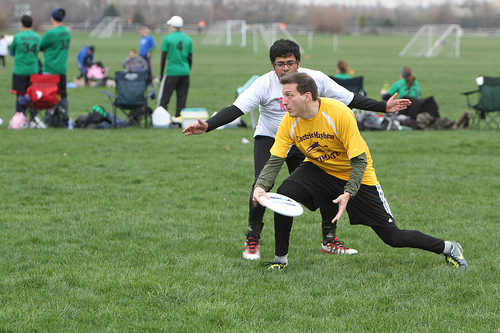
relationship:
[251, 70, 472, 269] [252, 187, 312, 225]
man holds frisbee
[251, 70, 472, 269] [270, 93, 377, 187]
man wears shirt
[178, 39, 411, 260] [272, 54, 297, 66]
man wears glasses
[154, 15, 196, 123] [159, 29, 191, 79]
man wears shirt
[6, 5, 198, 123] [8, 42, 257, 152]
people in field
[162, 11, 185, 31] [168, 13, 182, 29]
hat on head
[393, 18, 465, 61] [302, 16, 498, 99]
soccer goal in field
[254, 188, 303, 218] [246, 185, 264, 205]
frisbee on hand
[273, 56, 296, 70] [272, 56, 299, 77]
glasses on face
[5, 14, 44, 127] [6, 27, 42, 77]
man wears shirt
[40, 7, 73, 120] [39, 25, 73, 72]
man wears shirt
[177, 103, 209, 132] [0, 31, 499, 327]
cooler on field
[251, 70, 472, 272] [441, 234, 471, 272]
man wears shoe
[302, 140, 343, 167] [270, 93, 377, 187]
logo on shirt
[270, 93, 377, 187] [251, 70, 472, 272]
shirt on man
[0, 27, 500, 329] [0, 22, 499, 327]
grass on field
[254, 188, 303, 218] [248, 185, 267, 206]
frisbee in hand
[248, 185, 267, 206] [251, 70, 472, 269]
hand of man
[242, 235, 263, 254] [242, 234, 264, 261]
laces on sneaker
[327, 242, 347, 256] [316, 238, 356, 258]
laces on sneaker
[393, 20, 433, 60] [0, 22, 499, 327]
goal post on field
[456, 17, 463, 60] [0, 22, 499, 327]
goal post on field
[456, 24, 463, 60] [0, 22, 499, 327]
goal post on field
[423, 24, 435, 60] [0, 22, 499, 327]
goal post on field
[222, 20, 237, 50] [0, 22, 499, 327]
goal post on field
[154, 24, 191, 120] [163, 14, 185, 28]
man wearing hat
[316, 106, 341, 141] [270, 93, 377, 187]
stripe on shirt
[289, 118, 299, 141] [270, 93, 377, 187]
stripe on shirt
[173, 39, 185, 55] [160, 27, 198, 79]
number on shirt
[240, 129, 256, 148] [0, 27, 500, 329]
paper on grass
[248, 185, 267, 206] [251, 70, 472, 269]
hand on man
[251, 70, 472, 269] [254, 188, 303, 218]
man holding frisbee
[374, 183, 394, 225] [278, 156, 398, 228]
stripe on shorts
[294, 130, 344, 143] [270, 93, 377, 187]
word on shirt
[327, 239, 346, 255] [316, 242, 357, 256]
laces on sneaker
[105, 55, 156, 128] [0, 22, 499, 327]
chair on field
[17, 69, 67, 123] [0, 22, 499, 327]
chair on field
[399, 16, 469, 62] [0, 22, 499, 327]
soccer net on field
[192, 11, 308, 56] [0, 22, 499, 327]
soccer net on field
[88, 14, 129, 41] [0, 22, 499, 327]
soccer net on field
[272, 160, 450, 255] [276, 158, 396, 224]
pants under shorts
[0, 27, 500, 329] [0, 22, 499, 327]
grass in field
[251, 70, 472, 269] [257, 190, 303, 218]
man throwing frisbee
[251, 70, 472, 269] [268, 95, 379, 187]
man wearing pullover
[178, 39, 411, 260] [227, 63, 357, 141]
man wearing shirt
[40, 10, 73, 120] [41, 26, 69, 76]
man wearing jersey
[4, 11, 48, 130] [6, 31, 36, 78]
man wearing jersey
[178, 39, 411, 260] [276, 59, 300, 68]
man wearing glasses